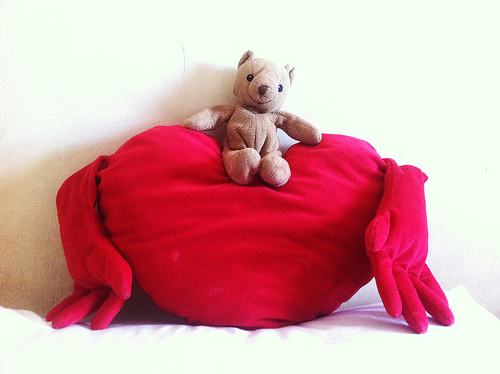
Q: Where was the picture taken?
A: The picture was taken indoors.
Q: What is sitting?
A: A stuffed animal.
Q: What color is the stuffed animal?
A: Light brown.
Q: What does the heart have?
A: It has arms.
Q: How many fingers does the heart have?
A: It has 10.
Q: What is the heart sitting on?
A: A bed.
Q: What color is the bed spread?
A: It is white.